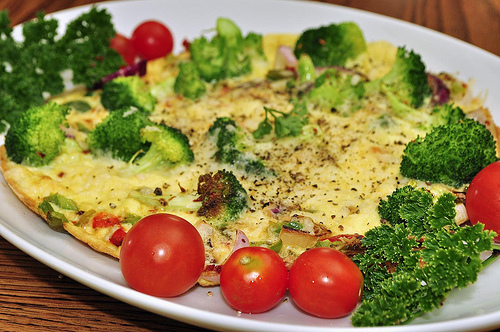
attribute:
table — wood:
[0, 0, 499, 328]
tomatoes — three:
[82, 179, 409, 321]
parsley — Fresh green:
[0, 7, 125, 119]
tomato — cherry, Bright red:
[96, 30, 135, 73]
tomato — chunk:
[119, 211, 208, 294]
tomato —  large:
[93, 203, 220, 302]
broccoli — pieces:
[135, 125, 193, 171]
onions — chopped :
[275, 42, 300, 77]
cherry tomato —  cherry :
[116, 215, 382, 308]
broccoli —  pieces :
[399, 118, 496, 183]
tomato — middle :
[220, 243, 287, 312]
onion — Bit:
[273, 224, 317, 253]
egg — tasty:
[0, 28, 497, 288]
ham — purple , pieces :
[266, 41, 372, 98]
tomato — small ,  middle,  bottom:
[101, 199, 221, 296]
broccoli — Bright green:
[0, 73, 197, 180]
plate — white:
[245, 318, 301, 329]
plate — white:
[3, 2, 498, 330]